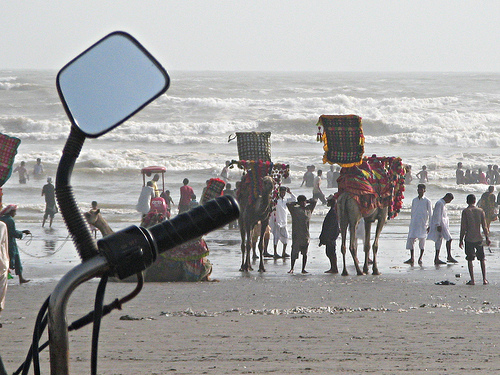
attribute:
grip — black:
[98, 193, 240, 280]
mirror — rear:
[29, 32, 161, 152]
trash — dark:
[435, 278, 455, 288]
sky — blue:
[90, 55, 142, 107]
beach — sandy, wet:
[1, 206, 498, 373]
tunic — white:
[406, 199, 429, 249]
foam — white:
[204, 90, 299, 110]